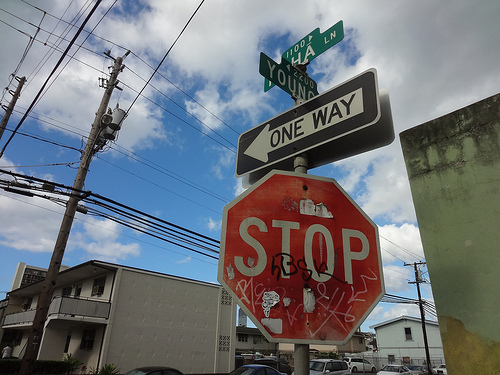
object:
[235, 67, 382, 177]
sign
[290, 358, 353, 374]
van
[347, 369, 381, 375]
road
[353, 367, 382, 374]
ground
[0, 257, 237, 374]
building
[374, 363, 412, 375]
car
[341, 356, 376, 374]
car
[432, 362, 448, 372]
car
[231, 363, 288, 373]
car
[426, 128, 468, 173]
ground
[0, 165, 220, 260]
wires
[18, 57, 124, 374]
pole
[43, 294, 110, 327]
balcony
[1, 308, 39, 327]
balcony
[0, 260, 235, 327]
second floor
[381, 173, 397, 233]
ground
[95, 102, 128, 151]
transformers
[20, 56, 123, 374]
poles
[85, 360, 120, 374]
bush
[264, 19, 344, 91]
sign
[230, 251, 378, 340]
grafiti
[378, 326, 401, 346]
white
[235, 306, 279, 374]
building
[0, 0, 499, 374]
scene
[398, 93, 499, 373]
stucture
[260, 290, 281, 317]
sticker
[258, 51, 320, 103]
street sign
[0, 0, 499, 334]
sky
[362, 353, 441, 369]
fence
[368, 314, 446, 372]
building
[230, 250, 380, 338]
graffiti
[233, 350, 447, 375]
parking lot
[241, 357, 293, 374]
cars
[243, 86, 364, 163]
arrow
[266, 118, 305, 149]
writing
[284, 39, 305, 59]
1100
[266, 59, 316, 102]
young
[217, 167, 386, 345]
stop sign